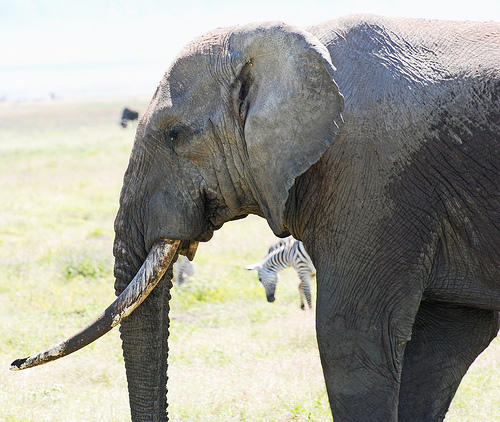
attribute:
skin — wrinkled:
[90, 7, 497, 418]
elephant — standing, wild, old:
[14, 17, 495, 420]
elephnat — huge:
[7, 19, 496, 419]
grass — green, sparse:
[4, 157, 125, 304]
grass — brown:
[0, 138, 300, 420]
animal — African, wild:
[6, 16, 497, 414]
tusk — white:
[11, 237, 182, 373]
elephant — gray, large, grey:
[81, 30, 484, 417]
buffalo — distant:
[116, 103, 140, 129]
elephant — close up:
[61, 34, 469, 358]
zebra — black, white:
[243, 236, 322, 311]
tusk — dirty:
[111, 172, 170, 402]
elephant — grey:
[87, 53, 340, 213]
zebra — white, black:
[246, 235, 316, 310]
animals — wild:
[5, 8, 484, 420]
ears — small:
[239, 17, 353, 245]